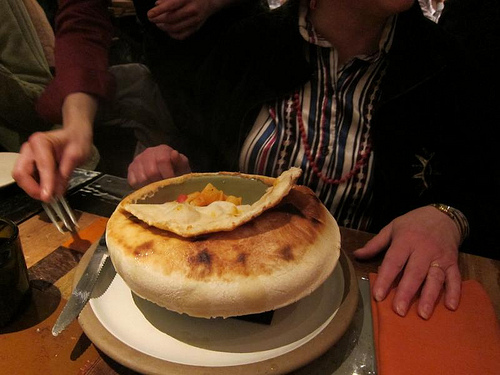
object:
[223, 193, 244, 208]
peaches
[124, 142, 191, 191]
hand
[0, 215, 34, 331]
glass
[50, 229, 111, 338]
knife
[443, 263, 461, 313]
finger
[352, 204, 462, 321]
hand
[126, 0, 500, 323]
woman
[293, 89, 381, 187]
necklace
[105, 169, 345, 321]
meal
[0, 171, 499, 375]
table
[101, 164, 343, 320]
crust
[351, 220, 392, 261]
finger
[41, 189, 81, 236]
fork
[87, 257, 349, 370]
plate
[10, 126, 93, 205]
hand